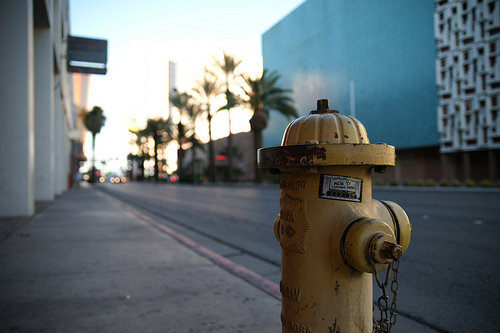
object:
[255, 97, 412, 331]
hydrant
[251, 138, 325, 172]
rust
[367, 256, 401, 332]
chain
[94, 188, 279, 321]
curb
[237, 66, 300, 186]
palmtree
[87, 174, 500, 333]
road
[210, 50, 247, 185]
palmtree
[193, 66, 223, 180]
palmtree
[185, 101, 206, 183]
palmtree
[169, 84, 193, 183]
palmtree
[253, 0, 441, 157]
wall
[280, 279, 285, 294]
letter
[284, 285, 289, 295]
letter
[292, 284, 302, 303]
letter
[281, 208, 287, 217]
letter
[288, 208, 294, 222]
letter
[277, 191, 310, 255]
logo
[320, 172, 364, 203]
sticker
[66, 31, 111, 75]
sign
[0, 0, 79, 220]
building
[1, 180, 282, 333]
sidewalk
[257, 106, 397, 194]
paint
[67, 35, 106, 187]
business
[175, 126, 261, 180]
business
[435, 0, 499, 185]
business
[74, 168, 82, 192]
man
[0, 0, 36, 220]
pillar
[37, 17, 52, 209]
pillar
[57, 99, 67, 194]
pillar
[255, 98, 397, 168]
cap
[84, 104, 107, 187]
palmtree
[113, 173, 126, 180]
car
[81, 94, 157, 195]
distance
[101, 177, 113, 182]
car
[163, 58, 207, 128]
billboard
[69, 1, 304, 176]
sky